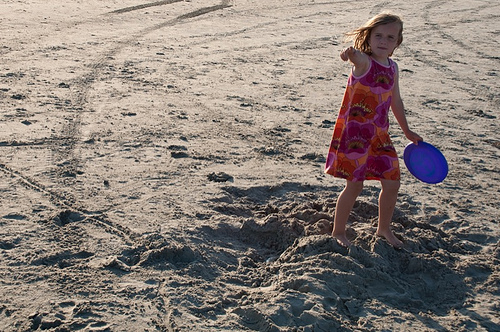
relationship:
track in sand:
[8, 132, 180, 264] [2, 1, 498, 329]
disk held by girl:
[396, 130, 453, 200] [317, 15, 442, 287]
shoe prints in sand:
[164, 127, 264, 218] [2, 1, 498, 329]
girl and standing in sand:
[330, 12, 422, 247] [0, 132, 498, 329]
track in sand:
[8, 132, 180, 264] [34, 87, 166, 267]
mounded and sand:
[208, 196, 458, 330] [79, 119, 179, 224]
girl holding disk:
[329, 12, 425, 255] [402, 141, 451, 185]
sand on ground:
[250, 187, 462, 318] [4, 8, 498, 326]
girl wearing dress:
[329, 12, 425, 255] [322, 50, 401, 182]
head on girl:
[346, 10, 419, 64] [321, 10, 465, 261]